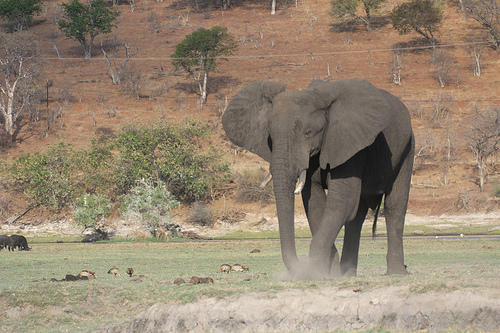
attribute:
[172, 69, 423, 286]
elephant — walking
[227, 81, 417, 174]
ears — big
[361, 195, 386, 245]
tail — long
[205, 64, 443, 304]
elephant — walking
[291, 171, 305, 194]
tusk — short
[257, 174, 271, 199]
tusk — short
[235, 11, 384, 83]
grass — brown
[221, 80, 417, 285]
elephant — large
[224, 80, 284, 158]
ear — large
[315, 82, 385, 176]
ear — large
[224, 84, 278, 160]
ear — large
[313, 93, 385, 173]
ear — large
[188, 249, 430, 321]
dust — stirred up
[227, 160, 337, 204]
tusks — ivory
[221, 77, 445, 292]
elephant — gray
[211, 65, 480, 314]
elephant — walking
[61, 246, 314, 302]
animals — laying down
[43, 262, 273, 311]
animals — laying down, brown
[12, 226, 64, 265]
animals — bending down, eating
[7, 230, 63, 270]
animals — eating, black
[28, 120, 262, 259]
tree — large, green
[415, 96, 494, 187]
trees — leafless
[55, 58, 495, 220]
dirt — large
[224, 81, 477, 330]
elephant — walking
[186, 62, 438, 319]
elephant — walking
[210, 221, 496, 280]
grass — walking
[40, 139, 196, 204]
bushes — piled